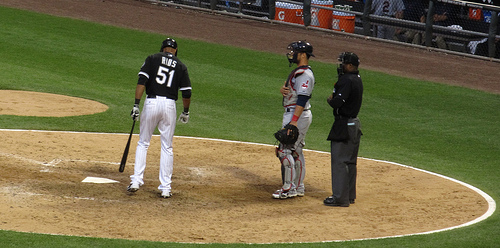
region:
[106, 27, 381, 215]
three guys standing on dirt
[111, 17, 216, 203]
guy wearing a black helmet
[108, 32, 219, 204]
guy wearing black and white shirt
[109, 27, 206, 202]
guy wearing white pants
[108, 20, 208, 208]
guy holding a black baseball bat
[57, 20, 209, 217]
guy near base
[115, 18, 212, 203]
guy wearing gloves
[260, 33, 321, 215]
guy wearing a face mask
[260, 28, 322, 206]
guy wearing a grey and red shirt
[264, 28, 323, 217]
guy wearing red and grey pants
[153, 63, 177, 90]
The number 51 on the player's uniform.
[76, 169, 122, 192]
Home plate.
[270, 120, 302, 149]
A baseball glove on the player's hand.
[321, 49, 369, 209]
An umpire for the baseball game.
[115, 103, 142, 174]
A baseball bat in the player's hand.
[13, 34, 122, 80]
Green grass on the baseball field.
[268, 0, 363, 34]
Three coolers behind the fence.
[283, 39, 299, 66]
A catcher's mask covering the player's face.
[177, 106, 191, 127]
A batting glove on the player's hand.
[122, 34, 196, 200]
A baseball player wearing a black and white uniform.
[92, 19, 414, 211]
the men are playing baseball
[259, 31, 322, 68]
the catcher is wearing a mask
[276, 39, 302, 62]
the mask is black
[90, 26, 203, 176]
the player is holding a bat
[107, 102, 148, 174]
the bat is black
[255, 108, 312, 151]
the catchers glove is black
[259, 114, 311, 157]
the glove is made of leather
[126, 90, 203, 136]
the player is wearing gloves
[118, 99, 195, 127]
the gloves are white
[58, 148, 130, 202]
home plate is white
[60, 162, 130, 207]
Home Plate on baseball field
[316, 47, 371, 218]
umpire of baseball game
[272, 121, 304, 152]
catchers glove on player's hand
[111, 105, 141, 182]
baseball bat in hand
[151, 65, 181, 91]
number on player's back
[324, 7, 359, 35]
water cooler behind fence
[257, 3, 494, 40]
fence behind the player's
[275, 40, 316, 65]
helmet on the player's head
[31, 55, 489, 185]
green grass of the field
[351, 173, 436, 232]
dirt in the catcher's circle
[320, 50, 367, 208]
this is a person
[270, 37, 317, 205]
this is a person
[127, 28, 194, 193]
this is a person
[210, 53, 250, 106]
a patch of green grass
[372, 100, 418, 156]
a patch of green grass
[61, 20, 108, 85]
a patch of green grass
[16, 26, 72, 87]
a patch of green grass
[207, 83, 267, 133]
a patch of green grass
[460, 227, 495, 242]
a patch of green grass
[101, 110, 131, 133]
a patch of green grass